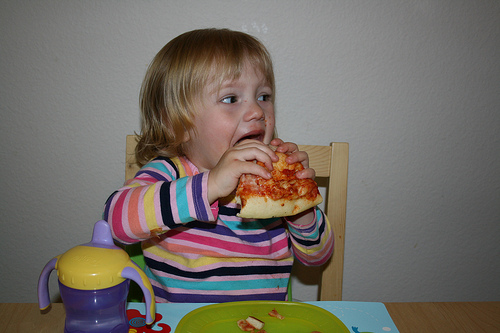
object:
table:
[0, 301, 500, 333]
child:
[101, 26, 338, 304]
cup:
[35, 219, 158, 332]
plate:
[171, 300, 354, 333]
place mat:
[123, 301, 401, 333]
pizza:
[234, 143, 324, 219]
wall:
[0, 0, 499, 304]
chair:
[123, 134, 350, 304]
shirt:
[100, 155, 337, 303]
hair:
[122, 27, 280, 168]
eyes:
[218, 93, 240, 105]